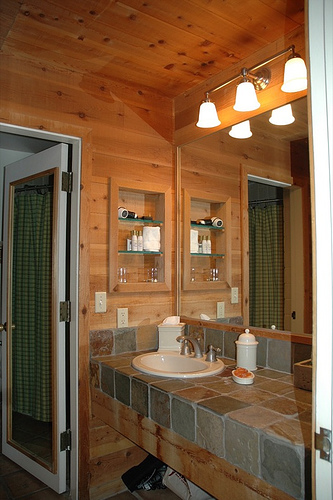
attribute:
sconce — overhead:
[195, 44, 307, 130]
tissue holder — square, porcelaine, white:
[157, 321, 185, 351]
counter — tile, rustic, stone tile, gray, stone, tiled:
[91, 347, 310, 448]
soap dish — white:
[232, 365, 256, 387]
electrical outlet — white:
[116, 306, 130, 330]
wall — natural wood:
[2, 59, 174, 499]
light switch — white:
[94, 290, 108, 313]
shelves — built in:
[107, 177, 174, 294]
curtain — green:
[12, 186, 54, 424]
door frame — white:
[1, 122, 85, 500]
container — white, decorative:
[235, 329, 259, 374]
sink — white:
[131, 349, 224, 379]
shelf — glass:
[116, 188, 164, 224]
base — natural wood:
[89, 384, 297, 500]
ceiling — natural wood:
[1, 1, 308, 101]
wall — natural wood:
[173, 24, 309, 147]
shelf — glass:
[116, 246, 163, 258]